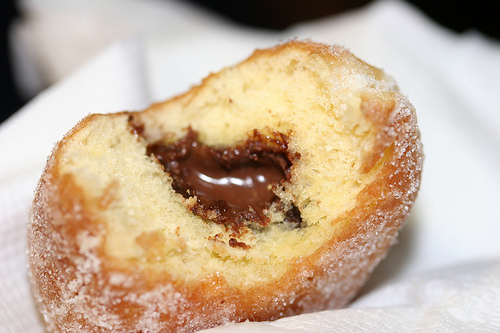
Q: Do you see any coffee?
A: No, there is no coffee.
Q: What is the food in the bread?
A: The food is chocolate.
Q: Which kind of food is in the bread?
A: The food is chocolate.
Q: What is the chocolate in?
A: The chocolate is in the bread.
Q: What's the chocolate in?
A: The chocolate is in the bread.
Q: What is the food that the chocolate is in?
A: The food is a bread.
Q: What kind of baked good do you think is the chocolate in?
A: The chocolate is in the bread.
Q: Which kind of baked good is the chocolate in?
A: The chocolate is in the bread.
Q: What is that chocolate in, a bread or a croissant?
A: The chocolate is in a bread.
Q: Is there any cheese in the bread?
A: No, there is chocolate in the bread.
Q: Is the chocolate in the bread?
A: Yes, the chocolate is in the bread.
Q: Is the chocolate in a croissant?
A: No, the chocolate is in the bread.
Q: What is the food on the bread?
A: The food is chocolate.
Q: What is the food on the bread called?
A: The food is chocolate.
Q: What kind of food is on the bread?
A: The food is chocolate.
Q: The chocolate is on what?
A: The chocolate is on the bread.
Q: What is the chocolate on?
A: The chocolate is on the bread.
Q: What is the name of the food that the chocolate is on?
A: The food is a bread.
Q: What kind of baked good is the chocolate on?
A: The chocolate is on the bread.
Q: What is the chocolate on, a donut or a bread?
A: The chocolate is on a bread.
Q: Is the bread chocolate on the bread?
A: Yes, the chocolate is on the bread.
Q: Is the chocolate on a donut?
A: No, the chocolate is on the bread.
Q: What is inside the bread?
A: The chocolate is inside the bread.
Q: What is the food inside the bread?
A: The food is chocolate.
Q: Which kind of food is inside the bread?
A: The food is chocolate.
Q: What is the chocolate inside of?
A: The chocolate is inside the bread.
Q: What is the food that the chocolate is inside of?
A: The food is a bread.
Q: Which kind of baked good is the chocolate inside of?
A: The chocolate is inside the bread.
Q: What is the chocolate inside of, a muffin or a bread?
A: The chocolate is inside a bread.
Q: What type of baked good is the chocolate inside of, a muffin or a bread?
A: The chocolate is inside a bread.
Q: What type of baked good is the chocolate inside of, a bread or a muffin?
A: The chocolate is inside a bread.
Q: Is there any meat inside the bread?
A: No, there is chocolate inside the bread.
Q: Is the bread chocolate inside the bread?
A: Yes, the chocolate is inside the bread.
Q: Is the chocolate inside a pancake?
A: No, the chocolate is inside the bread.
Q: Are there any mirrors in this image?
A: No, there are no mirrors.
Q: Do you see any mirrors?
A: No, there are no mirrors.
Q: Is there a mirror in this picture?
A: No, there are no mirrors.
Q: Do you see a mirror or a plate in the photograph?
A: No, there are no mirrors or plates.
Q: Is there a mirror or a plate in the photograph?
A: No, there are no mirrors or plates.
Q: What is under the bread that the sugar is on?
A: The napkin is under the bread.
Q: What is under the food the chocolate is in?
A: The napkin is under the bread.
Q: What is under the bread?
A: The napkin is under the bread.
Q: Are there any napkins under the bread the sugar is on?
A: Yes, there is a napkin under the bread.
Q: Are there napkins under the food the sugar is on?
A: Yes, there is a napkin under the bread.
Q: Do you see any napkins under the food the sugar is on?
A: Yes, there is a napkin under the bread.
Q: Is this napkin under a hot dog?
A: No, the napkin is under the bread.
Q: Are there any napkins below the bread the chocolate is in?
A: Yes, there is a napkin below the bread.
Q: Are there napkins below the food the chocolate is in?
A: Yes, there is a napkin below the bread.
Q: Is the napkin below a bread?
A: Yes, the napkin is below a bread.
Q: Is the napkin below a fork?
A: No, the napkin is below a bread.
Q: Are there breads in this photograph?
A: Yes, there is a bread.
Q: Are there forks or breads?
A: Yes, there is a bread.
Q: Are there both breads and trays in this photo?
A: No, there is a bread but no trays.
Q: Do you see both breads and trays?
A: No, there is a bread but no trays.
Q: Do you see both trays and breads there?
A: No, there is a bread but no trays.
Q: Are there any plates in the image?
A: No, there are no plates.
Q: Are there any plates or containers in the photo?
A: No, there are no plates or containers.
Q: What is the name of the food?
A: The food is a bread.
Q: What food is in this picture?
A: The food is a bread.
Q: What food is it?
A: The food is a bread.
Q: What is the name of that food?
A: This is a bread.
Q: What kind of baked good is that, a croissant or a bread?
A: This is a bread.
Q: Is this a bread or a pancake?
A: This is a bread.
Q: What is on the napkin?
A: The bread is on the napkin.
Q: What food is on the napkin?
A: The food is a bread.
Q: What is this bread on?
A: The bread is on the napkin.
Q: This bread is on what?
A: The bread is on the napkin.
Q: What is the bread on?
A: The bread is on the napkin.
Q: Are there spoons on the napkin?
A: No, there is a bread on the napkin.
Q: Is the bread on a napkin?
A: Yes, the bread is on a napkin.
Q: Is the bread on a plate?
A: No, the bread is on a napkin.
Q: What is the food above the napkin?
A: The food is a bread.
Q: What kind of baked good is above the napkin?
A: The food is a bread.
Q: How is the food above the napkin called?
A: The food is a bread.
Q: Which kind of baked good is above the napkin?
A: The food is a bread.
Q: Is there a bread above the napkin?
A: Yes, there is a bread above the napkin.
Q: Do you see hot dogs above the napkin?
A: No, there is a bread above the napkin.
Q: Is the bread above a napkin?
A: Yes, the bread is above a napkin.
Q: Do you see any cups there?
A: No, there are no cups.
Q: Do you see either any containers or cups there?
A: No, there are no cups or containers.